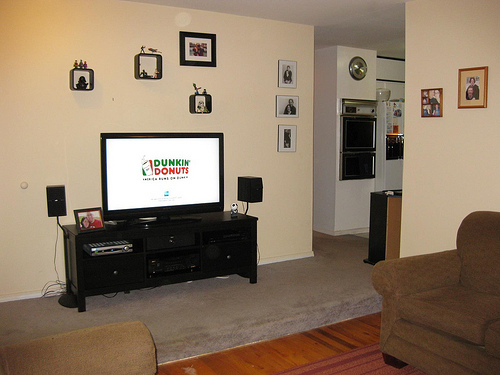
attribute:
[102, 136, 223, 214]
tv — flat screen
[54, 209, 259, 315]
stand — black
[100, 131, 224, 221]
tv — flat screen, large, on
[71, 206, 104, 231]
picture — framed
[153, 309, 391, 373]
floor — hardwood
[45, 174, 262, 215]
speakers — black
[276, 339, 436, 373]
rug — red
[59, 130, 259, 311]
entertainment set — black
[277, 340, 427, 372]
rug — red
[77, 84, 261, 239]
television — flat panel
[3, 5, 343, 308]
wall — cream color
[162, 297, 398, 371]
floor — hardwood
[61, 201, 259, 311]
entertainment center — black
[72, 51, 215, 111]
shelves — black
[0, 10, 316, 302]
wall — ivory painted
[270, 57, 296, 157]
picture — white, framed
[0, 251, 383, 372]
carpet — gray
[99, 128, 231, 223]
television — large, flat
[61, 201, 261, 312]
stand — black, dark, wooden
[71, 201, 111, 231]
photograph — framed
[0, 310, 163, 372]
sofa chair — brown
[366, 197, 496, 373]
sofa — brown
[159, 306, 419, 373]
floor — wooden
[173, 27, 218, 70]
picture — framed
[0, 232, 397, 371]
floor — gray, carpeted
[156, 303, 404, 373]
floor — hardwooden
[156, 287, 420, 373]
area rug — red, striped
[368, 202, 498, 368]
couch — brown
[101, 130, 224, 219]
screen — ad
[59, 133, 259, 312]
entertainment center — modest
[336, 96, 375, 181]
oven — double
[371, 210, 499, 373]
armchair — comfortable looking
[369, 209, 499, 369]
chair — brown, recliner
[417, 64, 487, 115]
photographs — family photographs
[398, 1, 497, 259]
wall — ivory